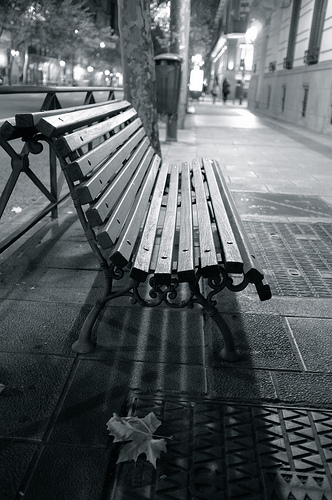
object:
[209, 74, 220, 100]
woman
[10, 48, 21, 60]
lights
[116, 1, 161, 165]
trunk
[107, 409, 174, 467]
leaf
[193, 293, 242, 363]
leg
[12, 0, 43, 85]
trees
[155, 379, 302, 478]
hole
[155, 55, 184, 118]
bin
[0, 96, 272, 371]
bench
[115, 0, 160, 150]
tree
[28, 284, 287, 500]
shadow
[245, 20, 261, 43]
lights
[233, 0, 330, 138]
building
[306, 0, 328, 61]
window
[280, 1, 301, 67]
window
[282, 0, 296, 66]
bars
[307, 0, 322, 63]
bars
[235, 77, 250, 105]
people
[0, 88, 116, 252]
fence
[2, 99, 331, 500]
sidewalk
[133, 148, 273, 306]
support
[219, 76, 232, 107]
person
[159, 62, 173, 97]
items